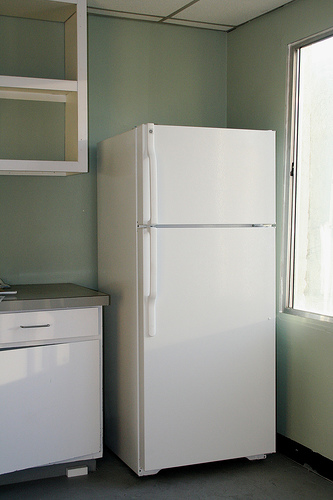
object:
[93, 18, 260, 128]
floor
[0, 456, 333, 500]
floor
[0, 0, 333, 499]
room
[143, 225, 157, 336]
handle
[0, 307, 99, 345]
drawer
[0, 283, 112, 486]
cabinet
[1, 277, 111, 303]
counter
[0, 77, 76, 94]
shelf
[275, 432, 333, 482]
moulding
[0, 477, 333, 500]
tiles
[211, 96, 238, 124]
ground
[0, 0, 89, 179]
cabinets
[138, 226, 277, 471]
door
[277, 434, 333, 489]
black border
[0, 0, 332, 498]
kitchen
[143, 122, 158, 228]
handle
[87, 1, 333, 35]
tile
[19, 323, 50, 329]
handle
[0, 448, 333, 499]
floor covering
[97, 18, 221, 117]
wall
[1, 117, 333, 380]
light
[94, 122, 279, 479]
freezer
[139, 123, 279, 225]
door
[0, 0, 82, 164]
doors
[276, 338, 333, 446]
wall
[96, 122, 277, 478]
refrigerator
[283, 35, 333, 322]
window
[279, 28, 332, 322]
frame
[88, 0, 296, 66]
frame